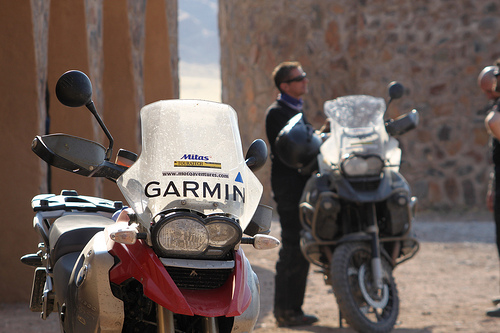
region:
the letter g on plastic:
[142, 180, 161, 198]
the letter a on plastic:
[163, 179, 181, 200]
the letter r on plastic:
[181, 179, 198, 198]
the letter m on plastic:
[200, 181, 220, 199]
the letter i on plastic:
[223, 183, 228, 201]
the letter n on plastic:
[232, 184, 245, 204]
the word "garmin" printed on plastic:
[143, 179, 246, 206]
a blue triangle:
[233, 170, 245, 183]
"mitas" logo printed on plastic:
[179, 152, 209, 162]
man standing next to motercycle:
[263, 59, 318, 325]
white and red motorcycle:
[21, 70, 277, 332]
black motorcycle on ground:
[289, 84, 429, 329]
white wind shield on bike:
[118, 99, 263, 232]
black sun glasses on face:
[283, 71, 307, 86]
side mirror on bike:
[55, 71, 120, 168]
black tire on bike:
[332, 237, 400, 332]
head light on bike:
[158, 214, 234, 255]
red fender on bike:
[111, 242, 253, 320]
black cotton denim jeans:
[271, 189, 310, 311]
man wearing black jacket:
[263, 54, 318, 330]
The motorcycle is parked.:
[11, 57, 286, 332]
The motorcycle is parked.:
[273, 72, 434, 332]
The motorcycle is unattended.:
[16, 62, 276, 330]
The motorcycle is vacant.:
[17, 44, 281, 331]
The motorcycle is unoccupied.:
[7, 58, 279, 332]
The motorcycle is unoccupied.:
[276, 78, 428, 331]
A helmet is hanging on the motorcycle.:
[273, 74, 428, 331]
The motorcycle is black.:
[269, 77, 428, 331]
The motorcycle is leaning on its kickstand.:
[275, 75, 432, 331]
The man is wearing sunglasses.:
[256, 49, 339, 330]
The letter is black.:
[136, 178, 163, 204]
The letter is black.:
[161, 176, 183, 199]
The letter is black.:
[178, 176, 203, 203]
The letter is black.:
[197, 175, 224, 202]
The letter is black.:
[219, 180, 232, 206]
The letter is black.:
[229, 181, 249, 206]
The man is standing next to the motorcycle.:
[260, 48, 425, 331]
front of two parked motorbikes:
[29, 69, 424, 331]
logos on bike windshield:
[144, 153, 245, 203]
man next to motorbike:
[266, 61, 322, 326]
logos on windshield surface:
[144, 154, 245, 202]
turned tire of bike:
[330, 240, 397, 330]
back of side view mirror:
[54, 69, 111, 149]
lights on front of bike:
[156, 217, 243, 259]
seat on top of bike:
[52, 213, 110, 258]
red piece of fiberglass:
[110, 237, 190, 316]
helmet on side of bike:
[277, 112, 321, 174]